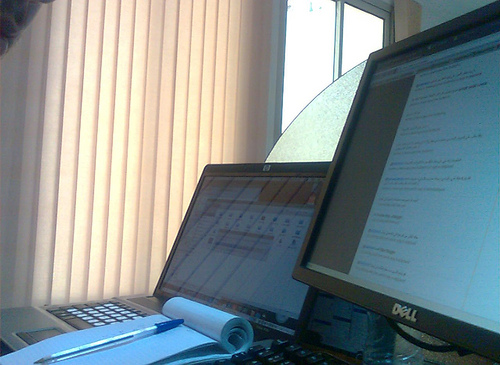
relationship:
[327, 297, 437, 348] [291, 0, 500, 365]
bottle behind dell monitor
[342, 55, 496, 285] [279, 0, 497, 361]
writing on a computer screen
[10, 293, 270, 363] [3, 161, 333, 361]
notepad on top of computer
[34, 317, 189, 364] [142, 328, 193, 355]
pen sitting on top of notepad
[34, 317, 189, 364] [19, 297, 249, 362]
pen on top of paper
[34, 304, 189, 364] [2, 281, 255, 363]
pen on notepad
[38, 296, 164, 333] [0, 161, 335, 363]
keyboard on laptop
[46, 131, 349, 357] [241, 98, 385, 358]
laptop on table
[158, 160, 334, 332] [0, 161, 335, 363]
screen on laptop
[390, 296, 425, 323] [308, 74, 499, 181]
logo on computer